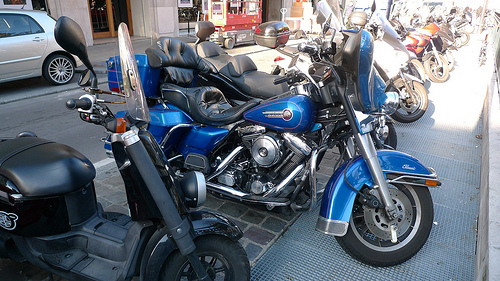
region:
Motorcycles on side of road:
[38, 8, 477, 276]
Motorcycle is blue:
[72, 27, 452, 264]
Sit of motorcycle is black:
[144, 34, 260, 124]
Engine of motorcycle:
[226, 127, 306, 192]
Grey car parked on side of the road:
[0, 3, 95, 96]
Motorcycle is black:
[6, 106, 258, 278]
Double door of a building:
[82, 0, 147, 43]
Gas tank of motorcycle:
[239, 89, 321, 138]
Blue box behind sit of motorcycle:
[104, 41, 164, 92]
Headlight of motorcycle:
[177, 161, 217, 211]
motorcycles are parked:
[55, 22, 384, 278]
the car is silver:
[2, 4, 145, 96]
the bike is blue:
[119, 57, 468, 279]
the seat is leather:
[144, 36, 217, 93]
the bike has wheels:
[292, 148, 454, 255]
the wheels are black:
[157, 235, 234, 275]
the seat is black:
[11, 135, 125, 210]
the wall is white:
[65, 10, 90, 27]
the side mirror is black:
[40, 7, 108, 74]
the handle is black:
[64, 97, 120, 128]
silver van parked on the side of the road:
[0, 7, 87, 89]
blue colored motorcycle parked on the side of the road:
[102, 30, 444, 270]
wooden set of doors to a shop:
[86, 0, 138, 45]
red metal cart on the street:
[201, 2, 262, 52]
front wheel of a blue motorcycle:
[318, 152, 440, 266]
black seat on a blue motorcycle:
[151, 34, 261, 124]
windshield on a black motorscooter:
[111, 20, 153, 123]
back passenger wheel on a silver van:
[41, 52, 78, 85]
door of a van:
[1, 11, 51, 78]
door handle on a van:
[31, 36, 43, 42]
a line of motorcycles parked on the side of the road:
[3, 22, 487, 278]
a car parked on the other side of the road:
[0, 11, 82, 88]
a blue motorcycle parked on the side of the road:
[111, 32, 445, 259]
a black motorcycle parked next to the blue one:
[0, 47, 250, 279]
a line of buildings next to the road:
[83, 4, 320, 34]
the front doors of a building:
[91, 6, 133, 38]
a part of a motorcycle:
[253, 23, 293, 48]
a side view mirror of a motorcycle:
[51, 12, 95, 87]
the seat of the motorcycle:
[171, 80, 254, 125]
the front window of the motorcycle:
[332, 169, 434, 261]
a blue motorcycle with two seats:
[106, 27, 444, 267]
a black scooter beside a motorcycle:
[1, 16, 253, 278]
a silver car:
[0, 6, 87, 87]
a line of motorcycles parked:
[104, 2, 479, 269]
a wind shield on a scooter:
[113, 20, 152, 124]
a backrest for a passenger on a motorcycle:
[146, 37, 214, 87]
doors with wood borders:
[88, 0, 135, 41]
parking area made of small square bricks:
[89, 124, 354, 279]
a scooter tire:
[158, 232, 253, 279]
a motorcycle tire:
[334, 160, 436, 268]